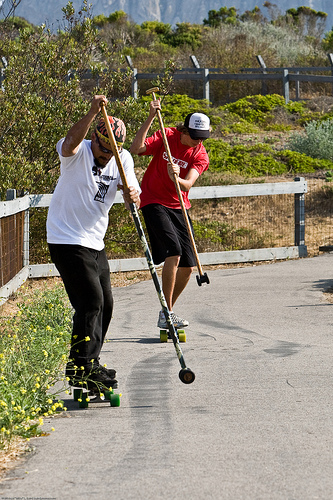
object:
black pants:
[46, 243, 113, 364]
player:
[47, 87, 210, 408]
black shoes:
[65, 361, 118, 392]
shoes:
[157, 311, 189, 329]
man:
[46, 95, 142, 391]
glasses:
[94, 133, 123, 154]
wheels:
[109, 394, 120, 407]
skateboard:
[60, 358, 122, 410]